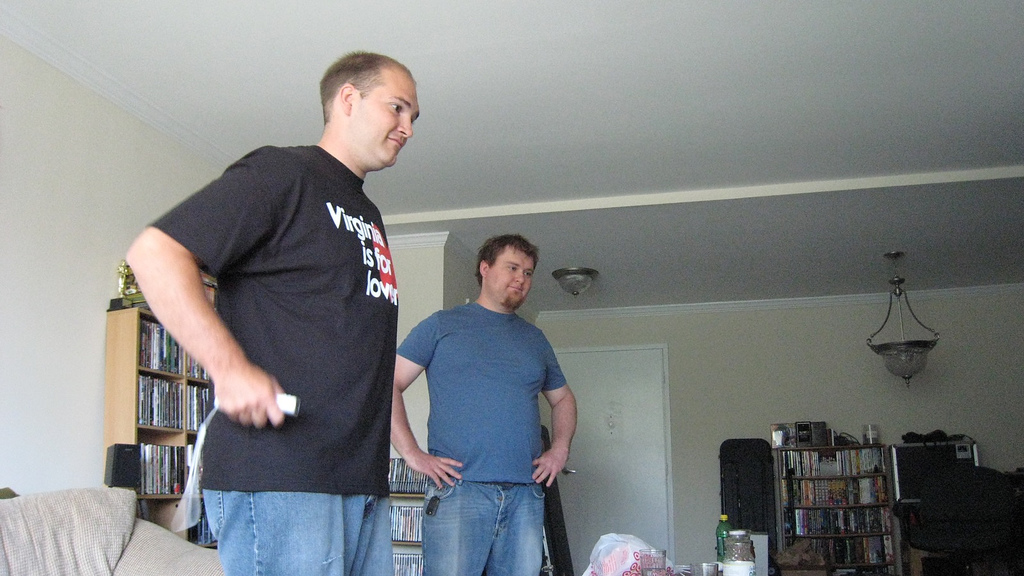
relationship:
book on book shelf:
[834, 509, 850, 532] [774, 441, 907, 572]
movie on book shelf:
[829, 446, 848, 475] [774, 444, 902, 574]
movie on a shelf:
[794, 503, 808, 532] [771, 449, 895, 573]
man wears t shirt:
[129, 49, 423, 572] [137, 146, 395, 502]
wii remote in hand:
[167, 380, 304, 542] [202, 355, 288, 425]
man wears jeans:
[389, 228, 582, 573] [421, 471, 552, 573]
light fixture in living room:
[859, 244, 946, 390] [0, 0, 1007, 574]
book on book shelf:
[803, 450, 823, 474] [774, 441, 907, 572]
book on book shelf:
[807, 446, 821, 475] [774, 441, 907, 572]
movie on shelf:
[799, 478, 812, 505] [771, 449, 895, 573]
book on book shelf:
[851, 469, 871, 505] [775, 449, 893, 573]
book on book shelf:
[828, 481, 847, 505] [774, 441, 907, 572]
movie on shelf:
[834, 509, 848, 533] [771, 449, 895, 573]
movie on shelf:
[838, 509, 851, 535] [771, 449, 895, 573]